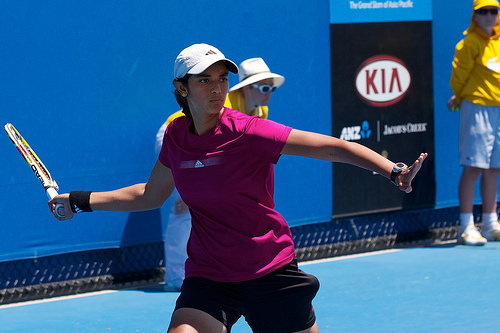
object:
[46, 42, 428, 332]
woman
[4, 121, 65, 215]
racket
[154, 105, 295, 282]
shirt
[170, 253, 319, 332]
shorts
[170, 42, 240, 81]
cap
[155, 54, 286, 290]
man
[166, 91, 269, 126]
shirt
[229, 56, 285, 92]
hat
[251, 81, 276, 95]
sunglasses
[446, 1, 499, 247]
man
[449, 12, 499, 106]
sweatshirt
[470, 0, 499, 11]
cap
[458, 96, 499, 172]
shorts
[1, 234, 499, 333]
court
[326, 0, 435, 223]
advertisement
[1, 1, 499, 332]
tennis court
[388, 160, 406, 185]
watch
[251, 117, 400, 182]
arm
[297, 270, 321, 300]
ball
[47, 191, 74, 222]
right hand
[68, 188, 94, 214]
wristband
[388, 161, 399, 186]
left wrist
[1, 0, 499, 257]
wall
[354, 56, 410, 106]
decal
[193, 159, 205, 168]
triangle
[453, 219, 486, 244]
shoes